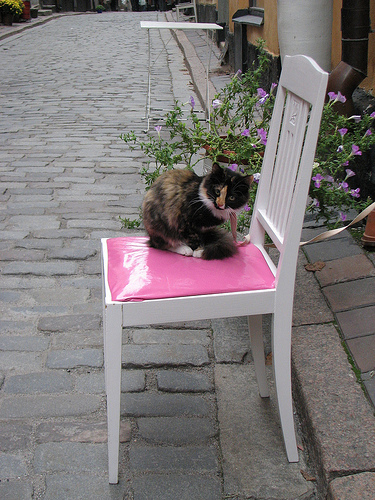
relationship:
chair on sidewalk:
[100, 53, 330, 485] [0, 10, 322, 498]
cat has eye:
[139, 161, 254, 256] [229, 195, 236, 202]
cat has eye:
[139, 161, 254, 256] [213, 187, 220, 195]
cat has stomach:
[139, 161, 254, 256] [197, 222, 222, 233]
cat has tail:
[139, 161, 254, 256] [204, 227, 238, 260]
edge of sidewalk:
[1, 9, 97, 44] [0, 10, 322, 498]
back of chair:
[248, 54, 329, 280] [100, 53, 330, 485]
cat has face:
[139, 161, 254, 256] [205, 174, 249, 211]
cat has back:
[139, 161, 254, 256] [143, 166, 198, 239]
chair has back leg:
[100, 53, 330, 485] [248, 315, 270, 399]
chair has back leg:
[100, 53, 330, 485] [271, 314, 299, 463]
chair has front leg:
[100, 53, 330, 485] [104, 304, 123, 485]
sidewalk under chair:
[0, 10, 322, 498] [100, 53, 330, 485]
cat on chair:
[139, 161, 254, 256] [100, 53, 330, 485]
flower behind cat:
[328, 91, 346, 109] [139, 161, 254, 256]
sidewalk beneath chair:
[0, 10, 322, 498] [100, 53, 330, 485]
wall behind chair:
[195, 0, 374, 138] [100, 53, 330, 485]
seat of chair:
[106, 235, 274, 303] [100, 53, 330, 485]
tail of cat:
[204, 227, 238, 260] [139, 161, 254, 256]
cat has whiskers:
[139, 161, 254, 256] [188, 190, 215, 219]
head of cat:
[206, 160, 255, 211] [139, 161, 254, 256]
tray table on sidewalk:
[140, 16, 221, 132] [0, 10, 322, 498]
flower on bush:
[328, 91, 346, 109] [126, 35, 374, 232]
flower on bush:
[250, 86, 270, 101] [126, 35, 374, 232]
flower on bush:
[345, 142, 362, 158] [126, 35, 374, 232]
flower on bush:
[343, 169, 356, 181] [126, 35, 374, 232]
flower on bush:
[338, 127, 349, 139] [126, 35, 374, 232]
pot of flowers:
[3, 12, 19, 25] [2, 0, 30, 18]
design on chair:
[285, 95, 303, 136] [100, 53, 330, 485]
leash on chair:
[230, 200, 374, 252] [100, 53, 330, 485]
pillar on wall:
[276, 1, 333, 71] [195, 0, 374, 138]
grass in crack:
[332, 319, 374, 404] [334, 322, 374, 406]